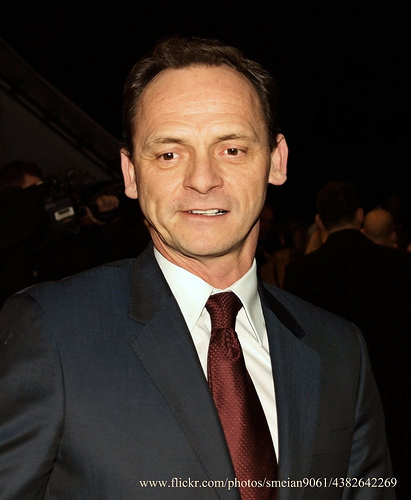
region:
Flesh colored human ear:
[257, 113, 316, 204]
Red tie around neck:
[184, 279, 274, 497]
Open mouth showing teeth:
[170, 196, 235, 225]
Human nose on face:
[179, 142, 226, 197]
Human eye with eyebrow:
[204, 126, 262, 164]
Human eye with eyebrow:
[139, 137, 190, 172]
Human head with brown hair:
[89, 26, 343, 281]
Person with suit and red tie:
[0, 36, 405, 493]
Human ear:
[108, 125, 150, 209]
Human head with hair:
[115, 25, 288, 271]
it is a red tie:
[207, 292, 286, 492]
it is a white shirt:
[170, 263, 295, 482]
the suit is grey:
[10, 283, 385, 494]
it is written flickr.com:
[135, 479, 221, 487]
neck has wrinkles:
[165, 248, 203, 273]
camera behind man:
[27, 169, 125, 231]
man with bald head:
[366, 207, 397, 244]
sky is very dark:
[12, 7, 410, 29]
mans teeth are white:
[199, 209, 218, 214]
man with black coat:
[285, 232, 410, 316]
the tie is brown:
[204, 290, 258, 417]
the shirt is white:
[164, 264, 286, 366]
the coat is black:
[35, 266, 360, 422]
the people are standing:
[308, 191, 403, 261]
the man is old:
[144, 98, 247, 137]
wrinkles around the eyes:
[144, 110, 264, 199]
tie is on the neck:
[186, 286, 299, 444]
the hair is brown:
[124, 47, 311, 101]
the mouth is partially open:
[180, 203, 265, 240]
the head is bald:
[359, 199, 400, 259]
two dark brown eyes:
[156, 143, 246, 161]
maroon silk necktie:
[204, 290, 276, 498]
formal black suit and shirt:
[0, 248, 409, 498]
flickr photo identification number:
[139, 475, 396, 490]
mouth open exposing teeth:
[179, 209, 230, 217]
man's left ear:
[266, 134, 289, 186]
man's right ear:
[118, 148, 138, 200]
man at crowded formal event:
[1, 1, 408, 498]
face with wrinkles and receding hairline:
[135, 62, 270, 253]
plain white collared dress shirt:
[152, 247, 278, 463]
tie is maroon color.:
[213, 336, 269, 459]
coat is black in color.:
[84, 374, 185, 470]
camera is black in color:
[14, 175, 66, 227]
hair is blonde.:
[135, 42, 260, 89]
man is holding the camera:
[44, 165, 115, 222]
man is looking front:
[114, 69, 284, 250]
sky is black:
[291, 43, 381, 148]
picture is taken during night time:
[34, 24, 396, 498]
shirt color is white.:
[172, 274, 204, 316]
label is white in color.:
[51, 208, 74, 221]